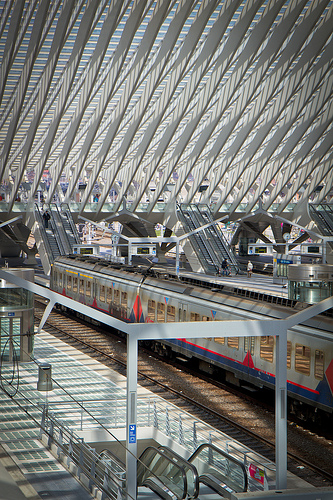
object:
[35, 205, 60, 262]
escalator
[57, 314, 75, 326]
gravel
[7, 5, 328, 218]
beams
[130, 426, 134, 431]
arrow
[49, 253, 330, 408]
train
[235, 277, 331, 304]
boarding area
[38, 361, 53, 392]
can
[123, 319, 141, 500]
supporting structure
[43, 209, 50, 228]
person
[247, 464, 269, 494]
pylons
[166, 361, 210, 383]
train tracks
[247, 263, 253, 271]
white dress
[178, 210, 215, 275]
escalator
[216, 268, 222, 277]
base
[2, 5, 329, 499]
station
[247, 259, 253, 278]
people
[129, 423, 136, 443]
sign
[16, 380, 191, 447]
platform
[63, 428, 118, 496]
handrail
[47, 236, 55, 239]
steps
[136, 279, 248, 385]
cars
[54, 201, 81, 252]
escalators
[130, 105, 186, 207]
ceiling structure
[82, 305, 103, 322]
stripe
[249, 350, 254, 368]
triangle